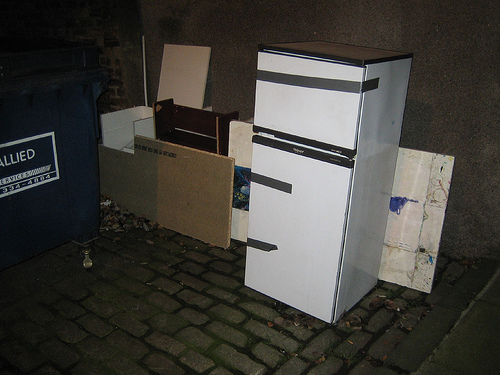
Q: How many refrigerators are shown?
A: One.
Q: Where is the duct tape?
A: On fridge.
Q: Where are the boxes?
A: On sidewalk.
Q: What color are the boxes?
A: Brown.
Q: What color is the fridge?
A: White.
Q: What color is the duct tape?
A: Silver.